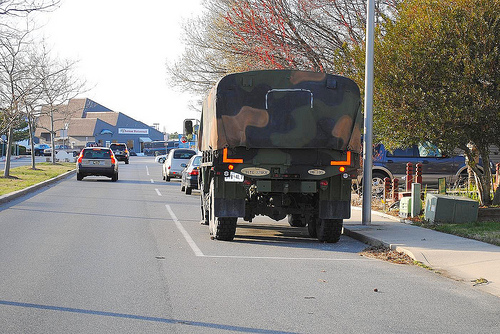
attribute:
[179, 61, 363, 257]
truck — military, green, army, moving, large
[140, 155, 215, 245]
road — clean, gray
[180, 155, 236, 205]
car — blue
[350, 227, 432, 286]
leaves — piled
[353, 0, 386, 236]
pole — silver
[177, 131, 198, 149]
sign — red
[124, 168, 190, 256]
street — dry, gray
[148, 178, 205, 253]
line — white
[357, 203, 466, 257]
sidewalk — gray, empty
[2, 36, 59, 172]
trees — bare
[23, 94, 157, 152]
roof — brown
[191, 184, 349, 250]
tires — large, black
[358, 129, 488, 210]
suv — parked, blue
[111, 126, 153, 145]
sign — white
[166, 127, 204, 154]
post — red